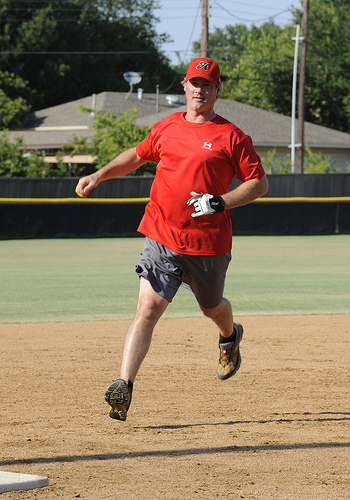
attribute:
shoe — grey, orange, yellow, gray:
[219, 323, 243, 381]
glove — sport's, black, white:
[186, 189, 226, 218]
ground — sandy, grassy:
[2, 233, 349, 500]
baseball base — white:
[1, 469, 47, 492]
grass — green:
[2, 239, 350, 322]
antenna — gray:
[122, 69, 142, 97]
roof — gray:
[4, 91, 350, 147]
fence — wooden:
[2, 176, 350, 235]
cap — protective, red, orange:
[183, 59, 219, 86]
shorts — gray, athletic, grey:
[135, 238, 230, 309]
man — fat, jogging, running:
[75, 57, 270, 421]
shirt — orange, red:
[135, 113, 264, 259]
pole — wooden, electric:
[200, 2, 210, 58]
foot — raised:
[106, 379, 132, 419]